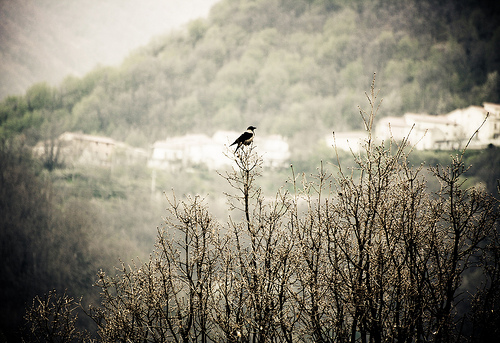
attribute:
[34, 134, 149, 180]
house — large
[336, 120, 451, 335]
branches — bare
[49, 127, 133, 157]
house — large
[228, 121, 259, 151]
bird — black, white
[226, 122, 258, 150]
bird — black, white, standing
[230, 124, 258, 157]
bird — black, white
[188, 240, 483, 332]
bush — dry, barren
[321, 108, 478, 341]
branches — dark, tree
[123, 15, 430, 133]
area — wooded, elevated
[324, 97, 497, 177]
building — white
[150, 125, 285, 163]
building — white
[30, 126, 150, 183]
building — white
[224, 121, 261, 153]
bird — black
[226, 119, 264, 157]
bird — black, white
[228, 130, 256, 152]
black — color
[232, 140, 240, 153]
tail — black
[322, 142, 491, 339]
tree — brown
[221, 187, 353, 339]
tree — brown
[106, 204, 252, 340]
tree — brown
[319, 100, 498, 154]
houses — in distance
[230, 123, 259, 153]
bird — pirched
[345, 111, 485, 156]
house — large